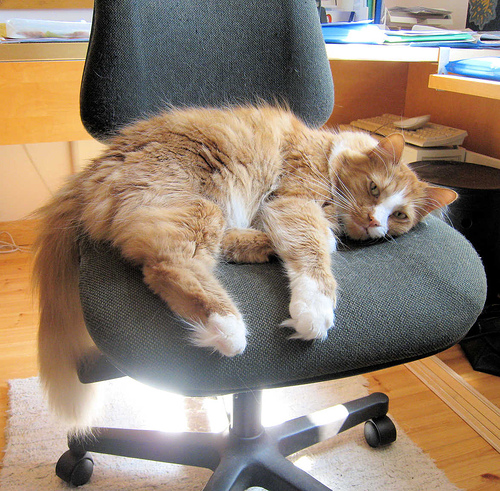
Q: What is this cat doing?
A: Napping.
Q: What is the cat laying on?
A: A chair.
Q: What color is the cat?
A: Orange and white.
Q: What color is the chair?
A: Grey.